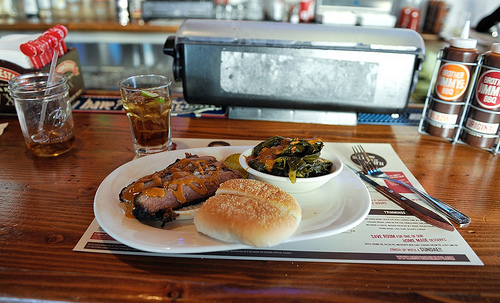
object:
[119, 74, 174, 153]
glass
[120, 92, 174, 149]
iced tea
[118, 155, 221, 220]
sauce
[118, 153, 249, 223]
meat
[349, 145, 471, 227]
fork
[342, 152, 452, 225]
knife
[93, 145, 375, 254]
plate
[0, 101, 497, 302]
table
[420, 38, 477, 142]
bbq sauce bottle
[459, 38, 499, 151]
bbq sauce bottle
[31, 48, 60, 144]
spoon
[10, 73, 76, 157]
jar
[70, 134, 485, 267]
table mat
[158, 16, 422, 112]
warmer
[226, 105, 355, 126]
grill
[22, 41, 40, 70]
spoon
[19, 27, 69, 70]
spoon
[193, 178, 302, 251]
bread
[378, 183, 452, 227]
handle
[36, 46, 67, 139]
straw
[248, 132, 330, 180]
vegetable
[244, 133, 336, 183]
topping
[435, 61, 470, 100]
label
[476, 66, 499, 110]
label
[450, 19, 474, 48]
top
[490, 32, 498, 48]
top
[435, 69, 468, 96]
mmm bbq word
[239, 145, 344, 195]
bowl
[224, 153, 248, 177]
pickle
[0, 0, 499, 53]
shelf